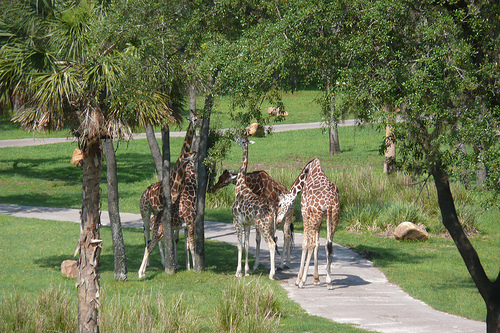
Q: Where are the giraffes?
A: Sidewalk.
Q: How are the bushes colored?
A: Light green.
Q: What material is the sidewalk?
A: Cement.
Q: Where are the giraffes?
A: Sunlight.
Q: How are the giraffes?
A: Shaded.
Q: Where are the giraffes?
A: In the park.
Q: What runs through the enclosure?
A: Trail.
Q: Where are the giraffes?
A: In the zoo.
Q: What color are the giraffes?
A: Brown.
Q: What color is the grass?
A: Green.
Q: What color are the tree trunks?
A: Brown.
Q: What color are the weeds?
A: Green.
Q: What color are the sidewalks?
A: Gray.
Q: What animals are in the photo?
A: Giraffes.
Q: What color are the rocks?
A: Brown.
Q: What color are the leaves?
A: Green.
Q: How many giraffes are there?
A: 5.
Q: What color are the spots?
A: Brown.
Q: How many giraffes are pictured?
A: Five.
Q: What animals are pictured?
A: Giraffes.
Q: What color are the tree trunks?
A: Brown.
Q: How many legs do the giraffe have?
A: Four.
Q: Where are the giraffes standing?
A: Underneath trees.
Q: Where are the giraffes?
A: In a park.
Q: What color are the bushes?
A: Green and brown.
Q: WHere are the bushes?
A: In the landscape.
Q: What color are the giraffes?
A: Brown and white.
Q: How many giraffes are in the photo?
A: 5.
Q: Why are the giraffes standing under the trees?
A: For shade.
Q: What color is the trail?
A: Grey.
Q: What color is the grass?
A: Green.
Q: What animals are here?
A: Giraffes.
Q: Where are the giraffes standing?
A: On the path and in the grass.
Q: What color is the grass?
A: Green.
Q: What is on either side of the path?
A: Grass.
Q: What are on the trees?
A: Leaves.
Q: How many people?
A: None.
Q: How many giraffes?
A: Four.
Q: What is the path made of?
A: Cement.